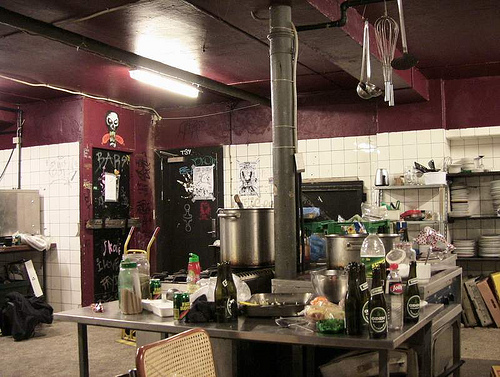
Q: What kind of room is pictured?
A: It is a kitchen.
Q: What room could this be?
A: It is a kitchen.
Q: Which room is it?
A: It is a kitchen.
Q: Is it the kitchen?
A: Yes, it is the kitchen.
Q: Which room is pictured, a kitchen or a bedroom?
A: It is a kitchen.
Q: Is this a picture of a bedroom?
A: No, the picture is showing a kitchen.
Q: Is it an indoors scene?
A: Yes, it is indoors.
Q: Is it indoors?
A: Yes, it is indoors.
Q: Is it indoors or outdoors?
A: It is indoors.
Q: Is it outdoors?
A: No, it is indoors.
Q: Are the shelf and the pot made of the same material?
A: Yes, both the shelf and the pot are made of metal.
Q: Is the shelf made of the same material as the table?
A: Yes, both the shelf and the table are made of metal.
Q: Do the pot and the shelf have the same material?
A: Yes, both the pot and the shelf are made of metal.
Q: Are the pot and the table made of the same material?
A: Yes, both the pot and the table are made of metal.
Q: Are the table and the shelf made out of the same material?
A: Yes, both the table and the shelf are made of metal.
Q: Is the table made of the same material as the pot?
A: Yes, both the table and the pot are made of metal.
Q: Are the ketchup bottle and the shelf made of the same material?
A: No, the ketchup bottle is made of plastic and the shelf is made of metal.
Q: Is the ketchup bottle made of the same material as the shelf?
A: No, the ketchup bottle is made of plastic and the shelf is made of metal.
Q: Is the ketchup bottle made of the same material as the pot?
A: No, the ketchup bottle is made of plastic and the pot is made of metal.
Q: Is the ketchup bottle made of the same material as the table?
A: No, the ketchup bottle is made of plastic and the table is made of metal.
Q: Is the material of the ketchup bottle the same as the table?
A: No, the ketchup bottle is made of plastic and the table is made of metal.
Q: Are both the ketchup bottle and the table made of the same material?
A: No, the ketchup bottle is made of plastic and the table is made of metal.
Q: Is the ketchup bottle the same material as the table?
A: No, the ketchup bottle is made of plastic and the table is made of metal.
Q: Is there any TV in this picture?
A: No, there are no televisions.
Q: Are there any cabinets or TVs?
A: No, there are no TVs or cabinets.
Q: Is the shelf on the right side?
A: Yes, the shelf is on the right of the image.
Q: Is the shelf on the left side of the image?
A: No, the shelf is on the right of the image.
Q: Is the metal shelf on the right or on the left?
A: The shelf is on the right of the image.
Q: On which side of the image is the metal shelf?
A: The shelf is on the right of the image.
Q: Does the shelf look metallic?
A: Yes, the shelf is metallic.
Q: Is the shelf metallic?
A: Yes, the shelf is metallic.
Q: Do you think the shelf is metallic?
A: Yes, the shelf is metallic.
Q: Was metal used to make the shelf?
A: Yes, the shelf is made of metal.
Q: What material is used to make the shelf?
A: The shelf is made of metal.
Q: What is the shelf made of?
A: The shelf is made of metal.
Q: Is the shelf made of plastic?
A: No, the shelf is made of metal.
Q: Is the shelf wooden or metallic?
A: The shelf is metallic.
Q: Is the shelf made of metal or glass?
A: The shelf is made of metal.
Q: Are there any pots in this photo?
A: Yes, there is a pot.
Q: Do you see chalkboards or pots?
A: Yes, there is a pot.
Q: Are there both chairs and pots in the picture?
A: Yes, there are both a pot and a chair.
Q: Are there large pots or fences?
A: Yes, there is a large pot.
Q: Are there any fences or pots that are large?
A: Yes, the pot is large.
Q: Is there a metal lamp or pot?
A: Yes, there is a metal pot.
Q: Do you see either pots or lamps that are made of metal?
A: Yes, the pot is made of metal.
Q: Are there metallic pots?
A: Yes, there is a metal pot.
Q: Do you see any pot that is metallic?
A: Yes, there is a pot that is metallic.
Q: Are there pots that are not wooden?
A: Yes, there is a metallic pot.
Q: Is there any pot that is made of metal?
A: Yes, there is a pot that is made of metal.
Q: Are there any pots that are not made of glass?
A: Yes, there is a pot that is made of metal.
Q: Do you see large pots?
A: Yes, there is a large pot.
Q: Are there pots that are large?
A: Yes, there is a pot that is large.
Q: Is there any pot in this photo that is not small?
A: Yes, there is a large pot.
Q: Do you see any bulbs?
A: No, there are no bulbs.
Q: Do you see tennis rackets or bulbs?
A: No, there are no bulbs or tennis rackets.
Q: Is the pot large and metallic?
A: Yes, the pot is large and metallic.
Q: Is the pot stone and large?
A: No, the pot is large but metallic.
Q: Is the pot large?
A: Yes, the pot is large.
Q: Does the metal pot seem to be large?
A: Yes, the pot is large.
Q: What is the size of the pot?
A: The pot is large.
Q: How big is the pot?
A: The pot is large.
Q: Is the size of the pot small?
A: No, the pot is large.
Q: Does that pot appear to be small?
A: No, the pot is large.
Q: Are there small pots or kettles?
A: No, there is a pot but it is large.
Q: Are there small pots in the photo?
A: No, there is a pot but it is large.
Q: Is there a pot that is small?
A: No, there is a pot but it is large.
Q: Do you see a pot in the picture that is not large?
A: No, there is a pot but it is large.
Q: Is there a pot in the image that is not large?
A: No, there is a pot but it is large.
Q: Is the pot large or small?
A: The pot is large.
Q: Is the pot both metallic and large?
A: Yes, the pot is metallic and large.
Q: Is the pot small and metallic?
A: No, the pot is metallic but large.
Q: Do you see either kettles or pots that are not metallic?
A: No, there is a pot but it is metallic.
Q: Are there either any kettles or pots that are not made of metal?
A: No, there is a pot but it is made of metal.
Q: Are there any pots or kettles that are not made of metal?
A: No, there is a pot but it is made of metal.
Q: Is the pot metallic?
A: Yes, the pot is metallic.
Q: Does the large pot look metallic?
A: Yes, the pot is metallic.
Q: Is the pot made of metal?
A: Yes, the pot is made of metal.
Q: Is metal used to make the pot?
A: Yes, the pot is made of metal.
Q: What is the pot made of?
A: The pot is made of metal.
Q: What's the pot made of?
A: The pot is made of metal.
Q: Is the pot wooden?
A: No, the pot is metallic.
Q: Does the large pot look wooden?
A: No, the pot is metallic.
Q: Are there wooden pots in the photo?
A: No, there is a pot but it is metallic.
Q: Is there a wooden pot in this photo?
A: No, there is a pot but it is metallic.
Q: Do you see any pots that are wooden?
A: No, there is a pot but it is metallic.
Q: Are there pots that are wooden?
A: No, there is a pot but it is metallic.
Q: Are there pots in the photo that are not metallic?
A: No, there is a pot but it is metallic.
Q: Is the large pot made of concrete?
A: No, the pot is made of metal.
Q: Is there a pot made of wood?
A: No, there is a pot but it is made of metal.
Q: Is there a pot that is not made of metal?
A: No, there is a pot but it is made of metal.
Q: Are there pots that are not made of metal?
A: No, there is a pot but it is made of metal.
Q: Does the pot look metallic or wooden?
A: The pot is metallic.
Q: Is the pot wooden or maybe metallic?
A: The pot is metallic.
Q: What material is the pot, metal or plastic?
A: The pot is made of metal.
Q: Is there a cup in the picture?
A: No, there are no cups.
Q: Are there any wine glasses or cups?
A: No, there are no cups or wine glasses.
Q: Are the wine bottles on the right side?
A: Yes, the wine bottles are on the right of the image.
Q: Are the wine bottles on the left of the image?
A: No, the wine bottles are on the right of the image.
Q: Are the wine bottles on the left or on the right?
A: The wine bottles are on the right of the image.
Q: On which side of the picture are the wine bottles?
A: The wine bottles are on the right of the image.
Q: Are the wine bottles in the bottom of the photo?
A: Yes, the wine bottles are in the bottom of the image.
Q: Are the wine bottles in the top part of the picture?
A: No, the wine bottles are in the bottom of the image.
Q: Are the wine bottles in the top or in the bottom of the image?
A: The wine bottles are in the bottom of the image.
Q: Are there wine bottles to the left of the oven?
A: Yes, there are wine bottles to the left of the oven.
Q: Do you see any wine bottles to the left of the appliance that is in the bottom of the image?
A: Yes, there are wine bottles to the left of the oven.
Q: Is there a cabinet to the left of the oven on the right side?
A: No, there are wine bottles to the left of the oven.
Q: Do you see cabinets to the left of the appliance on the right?
A: No, there are wine bottles to the left of the oven.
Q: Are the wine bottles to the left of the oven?
A: Yes, the wine bottles are to the left of the oven.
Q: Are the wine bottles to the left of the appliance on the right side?
A: Yes, the wine bottles are to the left of the oven.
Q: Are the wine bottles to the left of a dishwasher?
A: No, the wine bottles are to the left of the oven.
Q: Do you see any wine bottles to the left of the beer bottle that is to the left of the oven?
A: Yes, there are wine bottles to the left of the beer bottle.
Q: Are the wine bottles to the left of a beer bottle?
A: Yes, the wine bottles are to the left of a beer bottle.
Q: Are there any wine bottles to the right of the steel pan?
A: Yes, there are wine bottles to the right of the pan.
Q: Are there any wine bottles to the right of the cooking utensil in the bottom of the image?
A: Yes, there are wine bottles to the right of the pan.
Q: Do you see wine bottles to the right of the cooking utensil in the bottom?
A: Yes, there are wine bottles to the right of the pan.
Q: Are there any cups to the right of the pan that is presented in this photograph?
A: No, there are wine bottles to the right of the pan.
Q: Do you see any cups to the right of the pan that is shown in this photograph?
A: No, there are wine bottles to the right of the pan.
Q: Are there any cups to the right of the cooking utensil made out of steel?
A: No, there are wine bottles to the right of the pan.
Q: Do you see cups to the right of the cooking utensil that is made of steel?
A: No, there are wine bottles to the right of the pan.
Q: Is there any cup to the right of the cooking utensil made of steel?
A: No, there are wine bottles to the right of the pan.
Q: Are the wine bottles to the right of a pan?
A: Yes, the wine bottles are to the right of a pan.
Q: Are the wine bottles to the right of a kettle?
A: No, the wine bottles are to the right of a pan.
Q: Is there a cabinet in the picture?
A: No, there are no cabinets.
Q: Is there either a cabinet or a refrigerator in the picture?
A: No, there are no cabinets or refrigerators.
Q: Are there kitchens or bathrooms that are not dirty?
A: No, there is a kitchen but it is dirty.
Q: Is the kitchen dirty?
A: Yes, the kitchen is dirty.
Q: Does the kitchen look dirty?
A: Yes, the kitchen is dirty.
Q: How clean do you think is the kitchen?
A: The kitchen is dirty.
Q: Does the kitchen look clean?
A: No, the kitchen is dirty.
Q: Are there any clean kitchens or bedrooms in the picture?
A: No, there is a kitchen but it is dirty.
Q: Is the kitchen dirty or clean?
A: The kitchen is dirty.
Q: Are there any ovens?
A: Yes, there is an oven.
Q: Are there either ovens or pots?
A: Yes, there is an oven.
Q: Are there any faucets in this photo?
A: No, there are no faucets.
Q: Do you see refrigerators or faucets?
A: No, there are no faucets or refrigerators.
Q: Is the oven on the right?
A: Yes, the oven is on the right of the image.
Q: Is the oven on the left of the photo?
A: No, the oven is on the right of the image.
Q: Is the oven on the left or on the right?
A: The oven is on the right of the image.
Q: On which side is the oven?
A: The oven is on the right of the image.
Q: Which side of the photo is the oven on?
A: The oven is on the right of the image.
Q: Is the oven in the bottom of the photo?
A: Yes, the oven is in the bottom of the image.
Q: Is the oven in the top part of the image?
A: No, the oven is in the bottom of the image.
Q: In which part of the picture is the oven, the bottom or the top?
A: The oven is in the bottom of the image.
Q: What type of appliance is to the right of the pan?
A: The appliance is an oven.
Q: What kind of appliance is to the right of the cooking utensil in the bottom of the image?
A: The appliance is an oven.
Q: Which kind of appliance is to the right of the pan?
A: The appliance is an oven.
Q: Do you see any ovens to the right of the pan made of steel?
A: Yes, there is an oven to the right of the pan.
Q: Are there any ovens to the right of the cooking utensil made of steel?
A: Yes, there is an oven to the right of the pan.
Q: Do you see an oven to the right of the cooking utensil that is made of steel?
A: Yes, there is an oven to the right of the pan.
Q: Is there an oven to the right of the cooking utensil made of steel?
A: Yes, there is an oven to the right of the pan.